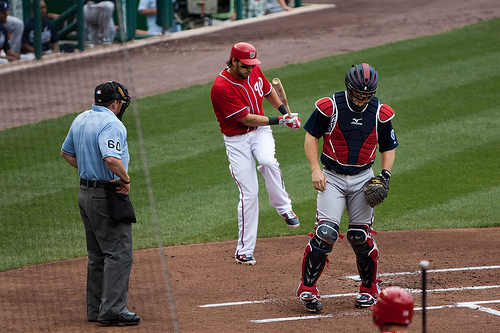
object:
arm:
[97, 129, 133, 183]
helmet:
[343, 62, 382, 95]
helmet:
[229, 41, 265, 66]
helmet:
[91, 80, 127, 106]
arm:
[215, 86, 277, 128]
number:
[106, 139, 118, 151]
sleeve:
[96, 125, 127, 161]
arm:
[301, 99, 327, 173]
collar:
[88, 101, 110, 112]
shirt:
[61, 103, 137, 187]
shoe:
[97, 309, 143, 325]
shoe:
[234, 251, 258, 266]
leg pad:
[293, 219, 345, 297]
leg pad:
[345, 222, 382, 294]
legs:
[225, 147, 262, 257]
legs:
[93, 211, 135, 313]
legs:
[299, 189, 347, 281]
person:
[366, 283, 418, 332]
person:
[23, 0, 65, 54]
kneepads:
[310, 216, 340, 252]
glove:
[363, 167, 394, 207]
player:
[206, 39, 302, 267]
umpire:
[61, 80, 147, 325]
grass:
[1, 18, 500, 274]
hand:
[308, 164, 328, 192]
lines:
[195, 294, 283, 310]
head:
[344, 62, 378, 108]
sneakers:
[355, 285, 380, 308]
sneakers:
[298, 288, 325, 313]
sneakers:
[280, 207, 302, 230]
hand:
[281, 110, 303, 132]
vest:
[321, 91, 382, 170]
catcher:
[295, 60, 399, 312]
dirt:
[2, 226, 500, 332]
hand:
[361, 172, 391, 209]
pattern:
[192, 134, 500, 252]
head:
[229, 40, 260, 78]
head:
[93, 80, 130, 116]